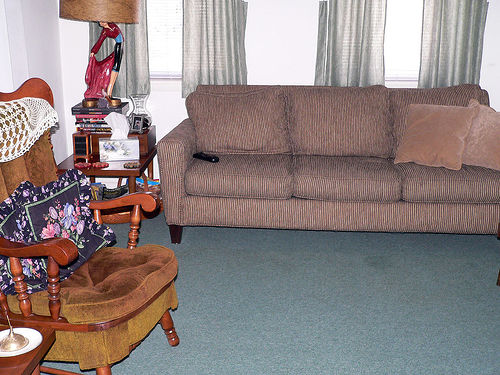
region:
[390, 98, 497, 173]
two throw pillows on a sofa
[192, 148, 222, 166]
remote control device on a sofa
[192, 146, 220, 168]
remote control device on a couch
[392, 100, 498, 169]
two throw pillows on a couch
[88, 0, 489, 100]
gray draperies on two windows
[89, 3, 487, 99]
gray curtains on two windows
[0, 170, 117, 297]
two throw pillows on a chair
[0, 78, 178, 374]
an uncomfortable chair for guests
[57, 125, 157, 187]
a small end table by the sofa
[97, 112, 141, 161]
a box of facial tissue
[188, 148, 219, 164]
a remote on couch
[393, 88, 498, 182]
two pillows on end of couch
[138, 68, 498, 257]
couch and pillows are brown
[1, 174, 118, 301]
two blue pillows on rocking chair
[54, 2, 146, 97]
lamp on end table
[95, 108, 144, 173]
box of tissues on end table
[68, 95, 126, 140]
stack of books on end table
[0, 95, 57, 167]
white doily on back of chair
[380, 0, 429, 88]
window is between curtains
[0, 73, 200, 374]
rocking chair is brown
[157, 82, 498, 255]
A brown couch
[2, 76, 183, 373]
A wooden chair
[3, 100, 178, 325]
A brownish cushion on the chair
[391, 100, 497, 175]
Two throw pillows on the couch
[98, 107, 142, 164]
A box of face tissue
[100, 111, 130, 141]
White face tissue sticking out of the box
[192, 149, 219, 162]
A black television remote control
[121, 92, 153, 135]
A crystal vase on the table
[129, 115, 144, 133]
A framed picture on the table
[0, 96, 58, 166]
A knitted head doily on the chair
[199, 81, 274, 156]
THAT IS A CAUTION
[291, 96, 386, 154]
THAT IS A CUSION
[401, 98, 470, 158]
THAT IS A CUSION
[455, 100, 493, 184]
THAT IS A CUSION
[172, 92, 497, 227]
THAT IS A CAUCH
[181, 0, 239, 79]
THAT IS A CURTAIN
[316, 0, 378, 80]
THAT IS A CURTAIN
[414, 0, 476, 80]
THAT IS A CURTAIN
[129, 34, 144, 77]
THAT IS A CURTAIN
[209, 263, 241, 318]
THAT IS A CARPET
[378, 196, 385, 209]
part of a chair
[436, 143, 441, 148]
part of a pillow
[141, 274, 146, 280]
edge of a chair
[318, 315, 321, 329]
part of the floor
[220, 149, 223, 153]
part of a remote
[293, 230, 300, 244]
edge of a leg